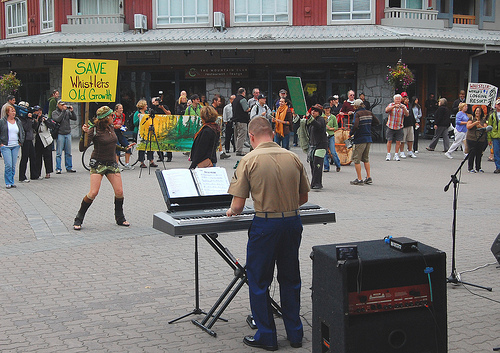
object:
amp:
[308, 236, 447, 353]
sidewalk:
[30, 207, 177, 328]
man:
[225, 116, 309, 350]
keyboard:
[152, 199, 335, 239]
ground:
[360, 177, 404, 222]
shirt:
[227, 141, 311, 212]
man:
[51, 100, 78, 174]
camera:
[67, 105, 72, 109]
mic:
[443, 125, 493, 292]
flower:
[382, 60, 417, 91]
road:
[349, 169, 490, 229]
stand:
[168, 233, 282, 338]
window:
[157, 1, 170, 24]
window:
[167, 1, 183, 23]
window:
[182, 1, 194, 22]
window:
[196, 0, 209, 21]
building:
[0, 0, 499, 140]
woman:
[304, 104, 329, 189]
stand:
[447, 179, 491, 293]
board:
[60, 57, 118, 103]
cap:
[96, 105, 114, 120]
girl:
[72, 105, 130, 231]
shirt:
[305, 114, 328, 149]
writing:
[67, 62, 115, 101]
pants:
[244, 209, 303, 343]